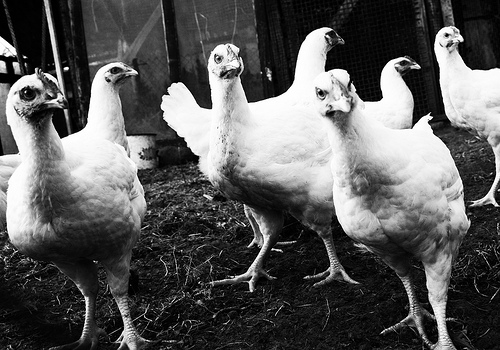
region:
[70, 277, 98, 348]
leg of a chicken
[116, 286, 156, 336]
of a chicken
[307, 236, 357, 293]
of a chicken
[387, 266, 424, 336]
of a chicken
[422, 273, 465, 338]
of a chicken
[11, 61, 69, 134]
head of a chicken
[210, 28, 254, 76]
head of a chicken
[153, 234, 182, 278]
Small grass in the dirt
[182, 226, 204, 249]
Small grass in the dirt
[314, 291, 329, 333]
Small grass in the dirt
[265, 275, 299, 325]
Small grass in the dirt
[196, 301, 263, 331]
Small grass in the dirt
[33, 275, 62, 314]
Small grass in the dirt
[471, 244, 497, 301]
Small grass in the dirt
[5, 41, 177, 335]
Two chickens standing in the dirt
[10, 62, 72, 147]
A death stare of a chicken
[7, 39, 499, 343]
several chickens standing together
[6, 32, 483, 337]
several white chickens together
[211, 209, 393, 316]
legs of a chicken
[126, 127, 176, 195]
a white pot in the back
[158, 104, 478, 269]
white feathers on chickens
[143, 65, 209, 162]
white tail feathers on chicken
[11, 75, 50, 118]
an eye of a chicken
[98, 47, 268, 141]
a fence in the background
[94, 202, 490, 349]
straw on the floor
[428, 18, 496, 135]
White chiclen on the ground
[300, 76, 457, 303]
White chiclen on the ground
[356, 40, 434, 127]
White chiclen on the ground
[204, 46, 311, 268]
White chiclen on the ground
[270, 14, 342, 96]
White chiclen on the ground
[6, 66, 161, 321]
White chiclen on the ground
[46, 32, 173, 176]
White chiclen on the ground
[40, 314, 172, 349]
Chicken feet on the ground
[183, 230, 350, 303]
Chicken feet on the ground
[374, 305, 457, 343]
Chicken feet on the ground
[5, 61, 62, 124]
head of a chicken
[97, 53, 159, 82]
head of a chicken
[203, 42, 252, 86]
head of a chicken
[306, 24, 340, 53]
head of a chicken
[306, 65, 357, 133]
head of a chicken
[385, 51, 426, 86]
head of a chicken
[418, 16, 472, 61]
head of a chicken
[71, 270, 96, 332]
leg of a chicken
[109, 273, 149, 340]
of a chicken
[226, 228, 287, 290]
of a chicken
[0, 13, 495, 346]
A bunch of white chickens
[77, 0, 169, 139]
a wood barn door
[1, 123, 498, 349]
the dirt floor of the barn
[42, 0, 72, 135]
a tall metal pole